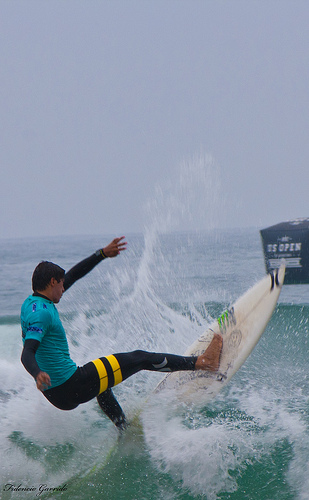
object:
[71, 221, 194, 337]
splush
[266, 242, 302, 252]
text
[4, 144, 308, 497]
foam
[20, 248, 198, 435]
swim suit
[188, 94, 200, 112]
ground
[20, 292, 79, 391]
shirt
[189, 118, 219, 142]
ground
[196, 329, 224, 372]
foot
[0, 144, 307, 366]
water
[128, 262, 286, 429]
board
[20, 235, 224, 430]
man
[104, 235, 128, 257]
hand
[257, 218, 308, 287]
box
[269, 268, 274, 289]
stripes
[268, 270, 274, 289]
stripes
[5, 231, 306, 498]
ocean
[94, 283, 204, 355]
waves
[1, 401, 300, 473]
waves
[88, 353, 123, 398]
line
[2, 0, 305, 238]
sky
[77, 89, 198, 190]
clouds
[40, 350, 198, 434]
pants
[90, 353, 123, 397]
stripes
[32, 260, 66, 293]
hair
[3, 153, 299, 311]
air